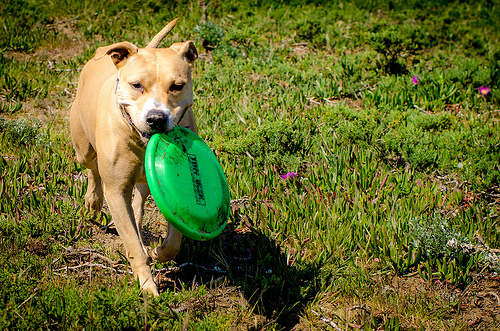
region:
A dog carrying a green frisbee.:
[67, 15, 232, 300]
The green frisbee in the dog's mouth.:
[141, 125, 226, 240]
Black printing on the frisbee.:
[185, 150, 205, 202]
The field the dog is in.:
[0, 0, 495, 325]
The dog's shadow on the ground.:
[156, 221, 331, 326]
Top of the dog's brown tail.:
[141, 15, 176, 45]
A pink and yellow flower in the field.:
[476, 81, 486, 91]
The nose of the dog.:
[142, 106, 167, 126]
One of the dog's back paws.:
[81, 176, 101, 211]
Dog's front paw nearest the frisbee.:
[147, 225, 184, 261]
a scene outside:
[10, 8, 497, 322]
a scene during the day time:
[9, 7, 488, 329]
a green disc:
[141, 109, 243, 258]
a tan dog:
[54, 15, 206, 305]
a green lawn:
[6, 5, 493, 330]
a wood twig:
[46, 242, 185, 295]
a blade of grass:
[316, 225, 331, 262]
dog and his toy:
[51, 16, 253, 310]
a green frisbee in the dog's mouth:
[135, 115, 256, 247]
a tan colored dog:
[48, 18, 256, 305]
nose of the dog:
[138, 102, 173, 142]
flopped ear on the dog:
[90, 35, 140, 77]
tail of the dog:
[135, 19, 179, 57]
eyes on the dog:
[126, 72, 187, 98]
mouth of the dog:
[114, 99, 149, 151]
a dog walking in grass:
[22, 12, 305, 324]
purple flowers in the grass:
[405, 65, 496, 106]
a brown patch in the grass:
[15, 20, 86, 65]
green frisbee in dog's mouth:
[118, 101, 235, 241]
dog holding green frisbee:
[65, 17, 207, 301]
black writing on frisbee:
[143, 127, 236, 239]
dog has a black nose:
[63, 16, 200, 296]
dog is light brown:
[66, 15, 204, 299]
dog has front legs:
[61, 16, 201, 300]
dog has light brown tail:
[69, 18, 202, 301]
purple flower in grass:
[374, 58, 499, 105]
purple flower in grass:
[371, 60, 498, 116]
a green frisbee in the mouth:
[137, 93, 249, 223]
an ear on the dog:
[107, 32, 139, 84]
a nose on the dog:
[140, 107, 170, 133]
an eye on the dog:
[152, 68, 207, 96]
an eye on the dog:
[110, 74, 150, 91]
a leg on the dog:
[95, 207, 171, 317]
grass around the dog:
[287, 179, 389, 264]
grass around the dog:
[260, 250, 311, 325]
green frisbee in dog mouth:
[128, 113, 243, 250]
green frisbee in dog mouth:
[134, 123, 243, 249]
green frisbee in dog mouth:
[130, 125, 252, 247]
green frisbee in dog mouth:
[132, 115, 238, 237]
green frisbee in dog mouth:
[132, 113, 237, 247]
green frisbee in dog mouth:
[137, 117, 233, 247]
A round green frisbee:
[133, 111, 240, 248]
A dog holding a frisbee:
[55, 10, 246, 305]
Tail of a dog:
[135, 10, 186, 55]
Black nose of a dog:
[135, 100, 175, 140]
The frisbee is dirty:
[136, 115, 236, 245]